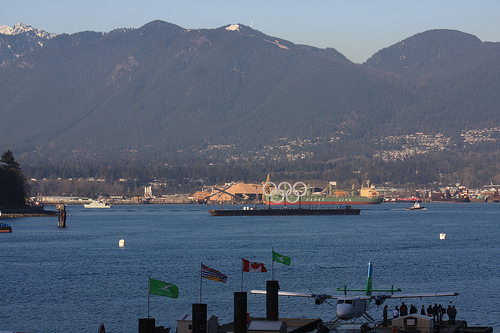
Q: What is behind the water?
A: Mountains.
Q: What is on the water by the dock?
A: Airplane.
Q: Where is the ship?
A: In the water.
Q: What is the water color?
A: Blue.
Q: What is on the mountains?
A: Trees.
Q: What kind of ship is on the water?
A: Cargo.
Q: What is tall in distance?
A: Mountain.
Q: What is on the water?
A: A boat.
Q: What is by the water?
A: Plane.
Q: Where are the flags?
A: Flying in the air.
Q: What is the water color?
A: Blue and calm.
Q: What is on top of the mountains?
A: Snow.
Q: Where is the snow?
A: On mountains.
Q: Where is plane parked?
A: On water.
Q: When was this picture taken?
A: Daytime.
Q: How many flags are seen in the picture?
A: Four.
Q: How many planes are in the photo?
A: One.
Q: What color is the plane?
A: White.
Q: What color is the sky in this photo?
A: Blue.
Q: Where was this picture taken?
A: A lake.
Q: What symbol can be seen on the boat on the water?
A: Olympic Rings.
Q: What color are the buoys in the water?
A: White.